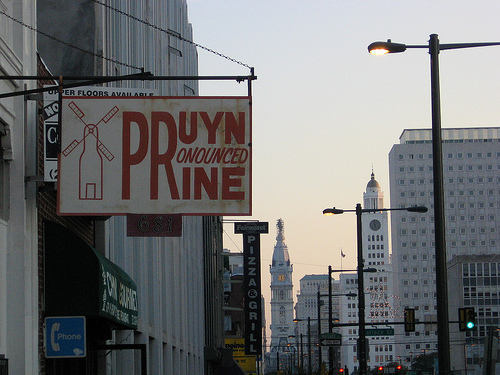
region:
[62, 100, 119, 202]
Illustration of a windmill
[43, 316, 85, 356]
telephone sign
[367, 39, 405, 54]
lit street light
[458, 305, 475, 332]
traffic signal with the green light illuminated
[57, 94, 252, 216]
white business sign with red lettering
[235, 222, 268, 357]
Pizza & Grill restaurant sign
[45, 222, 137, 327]
green canopy over a doorway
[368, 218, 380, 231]
clock face of a clocktower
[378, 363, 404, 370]
red traffic lights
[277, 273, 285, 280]
illuminated window of a tall building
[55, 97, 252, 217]
a red business sign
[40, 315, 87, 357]
a blue phone sign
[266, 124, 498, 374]
a beautiful city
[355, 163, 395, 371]
a tall clocktower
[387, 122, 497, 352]
a large office building with many windows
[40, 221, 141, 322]
a dark green canopy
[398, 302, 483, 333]
a pair of streetlights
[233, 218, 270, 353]
a large blue business sign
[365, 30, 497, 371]
a tall black lamp post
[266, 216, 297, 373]
a tall tower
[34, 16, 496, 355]
this is an urban setting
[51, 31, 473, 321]
this is taken outside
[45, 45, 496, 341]
this is a city street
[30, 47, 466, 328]
this looks like morning time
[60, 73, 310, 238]
this is store sign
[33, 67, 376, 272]
the sign says Pruyn onounced ine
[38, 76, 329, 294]
the sign is red and white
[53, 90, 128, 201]
there is a windmill on the sign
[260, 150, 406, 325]
these are towers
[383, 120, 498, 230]
this is a skyscraper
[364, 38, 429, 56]
an overhead street light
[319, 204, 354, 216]
an overhead street light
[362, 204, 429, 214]
an overhead street light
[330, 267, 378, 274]
an overhead street light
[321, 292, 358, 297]
an overhead street light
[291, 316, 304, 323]
an overhead street light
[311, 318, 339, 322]
an overhead street light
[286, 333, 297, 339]
an overhead street light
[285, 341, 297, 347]
an overhead street light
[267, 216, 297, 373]
large building in distance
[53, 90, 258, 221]
White sign with red lettering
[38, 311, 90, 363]
Blue phone sign with white lettering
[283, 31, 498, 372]
Row of street lights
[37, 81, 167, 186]
White sign with black letters behind the white sign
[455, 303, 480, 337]
Street light with a green light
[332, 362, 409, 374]
Three red streelights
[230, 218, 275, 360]
Black sign with white letters saying PIZZA GRILL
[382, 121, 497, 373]
Tallest white skyscraper to the right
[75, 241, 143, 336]
Green awing to the left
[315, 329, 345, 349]
Black street sign with one way arrow